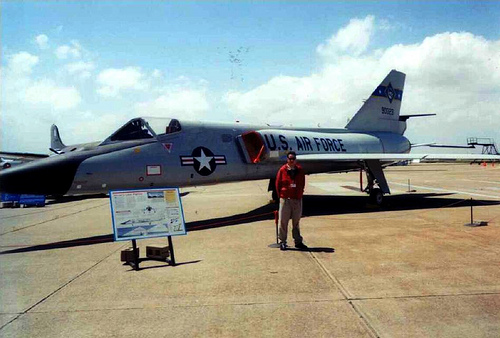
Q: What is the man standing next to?
A: Airplane.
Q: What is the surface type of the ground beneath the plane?
A: Concrete.